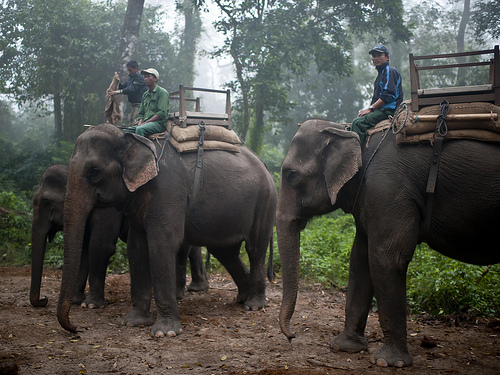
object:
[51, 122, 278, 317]
elephant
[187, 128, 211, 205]
strap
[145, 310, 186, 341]
toes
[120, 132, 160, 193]
ear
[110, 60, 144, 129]
man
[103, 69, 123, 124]
blanket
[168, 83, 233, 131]
seat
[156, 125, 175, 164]
rope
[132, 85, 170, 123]
shirt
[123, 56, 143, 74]
head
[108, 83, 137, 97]
arm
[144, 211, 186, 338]
leg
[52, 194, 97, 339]
trunk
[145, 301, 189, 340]
foot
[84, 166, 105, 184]
eye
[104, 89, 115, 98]
hand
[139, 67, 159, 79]
hat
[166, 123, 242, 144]
sacks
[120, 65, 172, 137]
rider